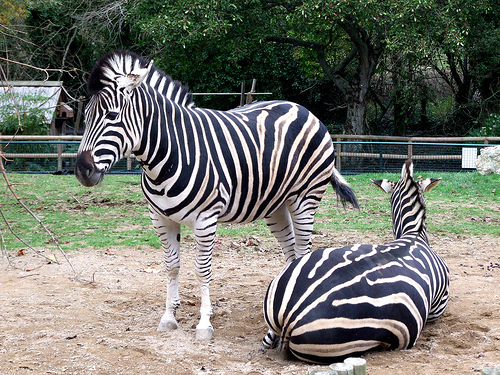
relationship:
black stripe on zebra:
[82, 73, 339, 286] [63, 56, 338, 357]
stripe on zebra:
[293, 300, 421, 347] [261, 159, 450, 366]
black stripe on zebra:
[266, 181, 451, 364] [261, 159, 450, 366]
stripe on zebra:
[366, 267, 406, 283] [261, 159, 450, 366]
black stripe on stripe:
[82, 73, 339, 286] [366, 257, 375, 264]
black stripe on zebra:
[280, 235, 419, 348] [261, 159, 450, 366]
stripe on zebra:
[344, 239, 384, 269] [259, 135, 469, 373]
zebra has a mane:
[74, 47, 360, 341] [88, 47, 197, 106]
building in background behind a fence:
[2, 77, 89, 172] [2, 129, 498, 186]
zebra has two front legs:
[74, 47, 360, 341] [133, 199, 228, 340]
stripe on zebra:
[205, 111, 245, 208] [74, 57, 324, 317]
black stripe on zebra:
[82, 73, 339, 286] [74, 47, 360, 341]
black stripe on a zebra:
[82, 73, 339, 286] [74, 47, 360, 341]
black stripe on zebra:
[146, 92, 180, 186] [74, 47, 360, 341]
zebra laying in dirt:
[261, 159, 450, 366] [1, 237, 499, 373]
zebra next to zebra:
[255, 157, 452, 373] [63, 56, 338, 357]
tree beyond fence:
[241, 4, 419, 172] [1, 140, 498, 174]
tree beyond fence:
[402, 0, 499, 140] [1, 140, 498, 174]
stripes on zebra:
[321, 249, 398, 357] [63, 56, 338, 357]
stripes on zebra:
[163, 113, 320, 208] [261, 159, 450, 366]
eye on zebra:
[104, 110, 119, 123] [74, 47, 360, 341]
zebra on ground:
[74, 47, 360, 341] [8, 221, 482, 361]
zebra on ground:
[255, 157, 452, 373] [433, 312, 498, 374]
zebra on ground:
[261, 159, 450, 366] [0, 170, 497, 373]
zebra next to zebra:
[261, 159, 450, 366] [261, 159, 450, 366]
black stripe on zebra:
[82, 73, 339, 286] [25, 22, 430, 372]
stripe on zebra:
[398, 213, 415, 223] [66, 62, 312, 264]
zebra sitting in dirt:
[261, 159, 450, 366] [4, 246, 477, 360]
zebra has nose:
[74, 47, 360, 341] [67, 155, 109, 195]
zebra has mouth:
[74, 47, 360, 341] [84, 162, 108, 189]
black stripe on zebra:
[266, 181, 451, 364] [65, 57, 400, 282]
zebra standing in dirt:
[261, 159, 450, 366] [62, 240, 470, 373]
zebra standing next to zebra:
[74, 47, 360, 341] [255, 157, 452, 373]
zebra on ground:
[74, 50, 359, 341] [9, 225, 495, 371]